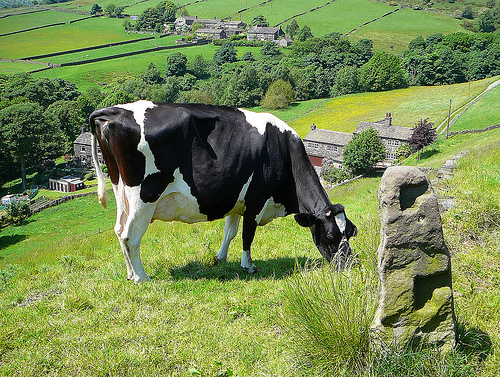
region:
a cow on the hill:
[80, 83, 369, 288]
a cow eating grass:
[85, 96, 361, 282]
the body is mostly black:
[135, 92, 343, 246]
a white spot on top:
[231, 87, 292, 137]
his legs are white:
[105, 173, 191, 280]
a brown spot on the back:
[84, 106, 146, 188]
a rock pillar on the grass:
[370, 163, 455, 352]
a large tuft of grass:
[273, 231, 406, 368]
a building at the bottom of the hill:
[67, 119, 114, 175]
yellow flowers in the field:
[288, 73, 478, 145]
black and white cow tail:
[78, 99, 119, 220]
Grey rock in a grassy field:
[360, 153, 480, 363]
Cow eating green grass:
[293, 191, 360, 287]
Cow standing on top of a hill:
[59, 78, 367, 298]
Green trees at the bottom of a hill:
[301, 43, 355, 79]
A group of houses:
[160, 10, 296, 57]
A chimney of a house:
[369, 106, 407, 131]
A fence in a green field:
[79, 52, 130, 62]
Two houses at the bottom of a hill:
[298, 112, 439, 174]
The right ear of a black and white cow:
[289, 202, 323, 233]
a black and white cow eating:
[72, 95, 359, 286]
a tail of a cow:
[83, 109, 118, 210]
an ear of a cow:
[291, 206, 316, 230]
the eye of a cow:
[319, 229, 336, 248]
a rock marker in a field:
[357, 156, 477, 368]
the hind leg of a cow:
[112, 150, 158, 290]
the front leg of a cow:
[235, 192, 263, 281]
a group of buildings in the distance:
[158, 11, 298, 51]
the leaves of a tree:
[6, 106, 49, 148]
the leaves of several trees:
[302, 44, 354, 94]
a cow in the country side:
[19, 14, 486, 336]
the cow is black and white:
[47, 65, 376, 307]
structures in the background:
[311, 106, 439, 176]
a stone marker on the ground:
[357, 158, 475, 357]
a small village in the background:
[139, 9, 302, 48]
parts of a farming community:
[6, 168, 95, 240]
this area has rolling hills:
[10, 13, 482, 344]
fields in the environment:
[10, 9, 479, 99]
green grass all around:
[80, 284, 348, 362]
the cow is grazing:
[262, 156, 382, 276]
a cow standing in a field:
[85, 101, 357, 291]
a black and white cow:
[83, 93, 359, 290]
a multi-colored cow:
[86, 98, 361, 287]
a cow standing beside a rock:
[81, 96, 464, 363]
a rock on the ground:
[372, 157, 457, 356]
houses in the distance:
[140, 9, 293, 53]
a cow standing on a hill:
[54, 101, 371, 285]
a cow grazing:
[83, 94, 363, 286]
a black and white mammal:
[80, 93, 360, 281]